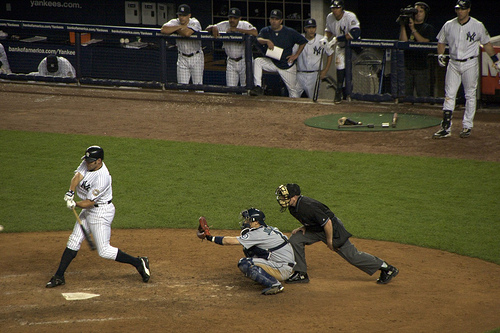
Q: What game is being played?
A: Baseball.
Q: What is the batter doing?
A: Swinging at the ball.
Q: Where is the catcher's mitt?
A: Catcher's left hand.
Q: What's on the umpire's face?
A: Safety face mask.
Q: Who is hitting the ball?
A: Batter.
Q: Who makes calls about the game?
A: Umpire.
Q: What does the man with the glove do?
A: Catches the ball.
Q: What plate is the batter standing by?
A: Home plate.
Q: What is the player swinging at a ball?
A: A bat.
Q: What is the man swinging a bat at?
A: A baseball.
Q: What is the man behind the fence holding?
A: A video camera.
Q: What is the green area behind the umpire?
A: Grass.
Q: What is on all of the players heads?
A: Baseball caps.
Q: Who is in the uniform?
A: Player.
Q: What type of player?
A: Baseball.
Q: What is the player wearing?
A: Uniform.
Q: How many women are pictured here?
A: Zero.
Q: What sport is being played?
A: Baseball.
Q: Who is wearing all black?
A: The umpire.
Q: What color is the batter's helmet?
A: Black.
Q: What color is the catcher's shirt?
A: Grey.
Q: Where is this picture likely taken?
A: A baseball Stadium.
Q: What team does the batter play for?
A: The New York Yankees.